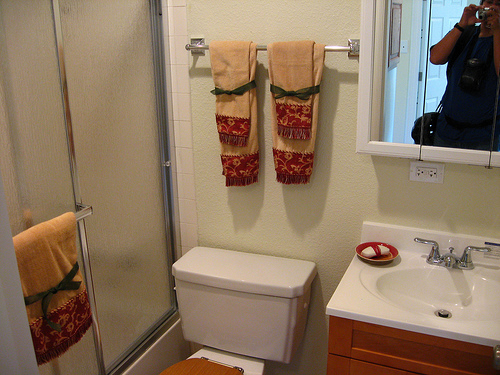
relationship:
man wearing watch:
[426, 11, 498, 155] [451, 15, 469, 37]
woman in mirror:
[426, 11, 498, 155] [350, 8, 497, 160]